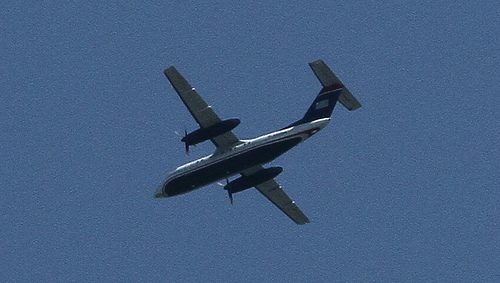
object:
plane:
[153, 58, 363, 224]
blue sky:
[2, 0, 499, 281]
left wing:
[161, 65, 242, 148]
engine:
[174, 117, 239, 154]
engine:
[218, 166, 285, 204]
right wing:
[240, 163, 316, 224]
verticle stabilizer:
[304, 58, 362, 122]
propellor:
[175, 127, 199, 154]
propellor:
[216, 174, 236, 206]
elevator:
[196, 105, 214, 111]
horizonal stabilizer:
[272, 182, 283, 189]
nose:
[151, 173, 176, 197]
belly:
[165, 135, 307, 196]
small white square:
[315, 98, 327, 108]